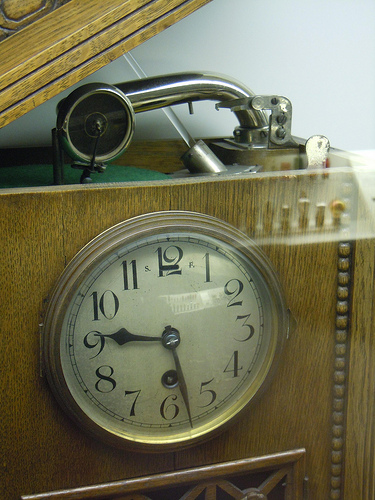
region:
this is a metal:
[110, 74, 233, 117]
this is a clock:
[51, 241, 293, 410]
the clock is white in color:
[186, 304, 234, 348]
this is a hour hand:
[97, 329, 161, 352]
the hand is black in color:
[107, 329, 138, 344]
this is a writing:
[90, 288, 122, 315]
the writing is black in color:
[88, 289, 119, 325]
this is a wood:
[313, 240, 350, 369]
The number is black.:
[192, 236, 219, 292]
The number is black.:
[217, 275, 248, 310]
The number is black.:
[225, 309, 258, 344]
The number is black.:
[217, 342, 245, 386]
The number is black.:
[193, 371, 219, 412]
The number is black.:
[155, 390, 185, 424]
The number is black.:
[121, 381, 146, 422]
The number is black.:
[86, 360, 121, 399]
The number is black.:
[82, 285, 121, 324]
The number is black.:
[115, 255, 139, 296]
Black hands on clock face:
[95, 327, 206, 430]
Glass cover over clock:
[43, 211, 291, 453]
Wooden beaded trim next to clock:
[328, 180, 353, 498]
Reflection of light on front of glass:
[164, 285, 236, 314]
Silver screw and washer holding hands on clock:
[165, 333, 177, 345]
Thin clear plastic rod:
[122, 53, 200, 145]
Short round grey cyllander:
[179, 138, 228, 174]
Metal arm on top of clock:
[50, 69, 307, 182]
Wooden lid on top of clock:
[0, 1, 212, 127]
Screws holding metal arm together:
[276, 114, 286, 138]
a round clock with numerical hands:
[41, 209, 292, 452]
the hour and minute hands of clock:
[86, 325, 208, 427]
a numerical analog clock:
[40, 220, 280, 454]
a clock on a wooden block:
[4, 181, 373, 499]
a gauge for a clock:
[42, 80, 140, 166]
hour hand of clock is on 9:
[37, 214, 286, 448]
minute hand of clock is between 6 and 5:
[40, 206, 293, 455]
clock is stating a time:
[33, 208, 290, 452]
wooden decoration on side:
[309, 174, 357, 496]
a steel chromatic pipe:
[129, 70, 267, 125]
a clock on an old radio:
[55, 207, 321, 464]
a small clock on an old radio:
[65, 216, 310, 422]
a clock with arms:
[43, 213, 318, 453]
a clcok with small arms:
[55, 183, 340, 449]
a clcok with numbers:
[40, 218, 293, 498]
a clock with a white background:
[11, 226, 324, 470]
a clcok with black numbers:
[51, 218, 244, 417]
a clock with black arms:
[76, 226, 282, 439]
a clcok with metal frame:
[43, 216, 324, 486]